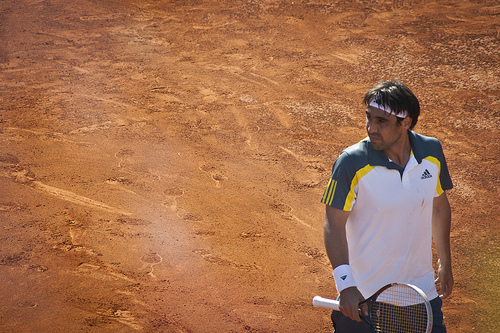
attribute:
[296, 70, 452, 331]
shirt — yellow, blue, white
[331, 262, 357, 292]
band — white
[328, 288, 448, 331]
shorts — blue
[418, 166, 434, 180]
insignia — blue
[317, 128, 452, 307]
shirt — white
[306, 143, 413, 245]
stripes — yellow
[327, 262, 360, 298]
wristband — white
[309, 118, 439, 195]
blue shirt — yellow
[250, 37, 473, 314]
shirt — mostly white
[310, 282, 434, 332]
racket — white, black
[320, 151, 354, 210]
sleeve — blue, yellow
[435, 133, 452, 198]
sleeve — blue, yellow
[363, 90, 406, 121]
head band — white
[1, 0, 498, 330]
ground — brown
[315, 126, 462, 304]
shirt — blue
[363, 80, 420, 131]
hair — dark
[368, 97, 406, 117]
headband — white